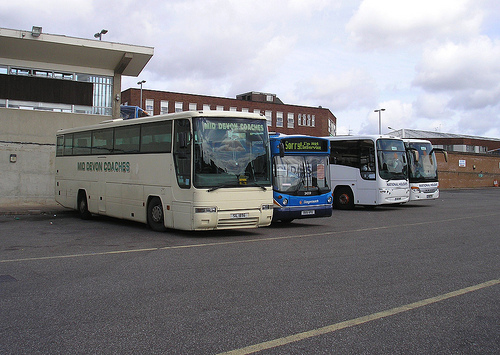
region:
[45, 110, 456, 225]
Four buses parked together.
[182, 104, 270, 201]
Large window on the white bus.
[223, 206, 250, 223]
License plate on the white bus.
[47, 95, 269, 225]
The white bus is a tour bus.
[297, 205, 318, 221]
License plate on the blue bus.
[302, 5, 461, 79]
Blue sky filled with clouds.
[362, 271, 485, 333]
White line on the road.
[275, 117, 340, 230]
Blue bus is a city bus.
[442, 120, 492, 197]
Brick building beside the buses.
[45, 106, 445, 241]
buses parked in parking lot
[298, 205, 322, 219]
license plate on front of bus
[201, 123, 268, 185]
windshield on bus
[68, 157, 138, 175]
name of bus carrier on side of bus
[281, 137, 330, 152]
digital window on front of bus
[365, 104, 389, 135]
tall street lamp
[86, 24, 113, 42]
lights on top of roof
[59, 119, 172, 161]
windows on side of bus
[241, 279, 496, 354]
white line in street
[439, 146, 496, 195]
brick wall in parking lot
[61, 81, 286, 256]
white bus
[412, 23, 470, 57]
white clouds in blue sky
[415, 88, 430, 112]
white clouds in blue sky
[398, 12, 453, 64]
white clouds in blue sky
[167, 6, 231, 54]
white clouds in blue sky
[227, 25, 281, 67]
white clouds in blue sky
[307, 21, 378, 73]
white clouds in blue sky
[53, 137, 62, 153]
window on the side of the bus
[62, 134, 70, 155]
window on the side of the bus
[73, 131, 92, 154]
window on the side of the bus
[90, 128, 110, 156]
window on the side of the bus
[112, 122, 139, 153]
window on the side of the bus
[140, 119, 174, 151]
window on the side of the bus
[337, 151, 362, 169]
window on the side of the bus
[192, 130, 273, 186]
windshield on passenger bus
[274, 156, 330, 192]
windshield on passenger bus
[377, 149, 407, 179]
windshield on passenger bus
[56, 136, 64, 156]
window on side of bus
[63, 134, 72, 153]
window on side of bus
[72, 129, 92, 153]
window on side of bus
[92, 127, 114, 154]
window on side of bus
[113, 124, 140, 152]
window on side of bus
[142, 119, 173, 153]
window on side of bus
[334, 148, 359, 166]
window on side of bus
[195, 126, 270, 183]
windshield on passenger bus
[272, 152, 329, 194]
windshield on passenger bus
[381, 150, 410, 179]
windshield on passenger bus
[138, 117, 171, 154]
A window on a vehicle.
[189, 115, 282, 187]
A window on a vehicle.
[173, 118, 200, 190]
A window on a vehicle.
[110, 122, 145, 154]
A window on a vehicle.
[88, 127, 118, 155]
A window on a vehicle.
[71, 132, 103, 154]
A window on a vehicle.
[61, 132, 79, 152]
A window on a vehicle.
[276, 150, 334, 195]
A window on a vehicle.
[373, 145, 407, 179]
A window on a vehicle.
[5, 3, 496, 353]
a scene during the day time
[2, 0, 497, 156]
a sky with clouds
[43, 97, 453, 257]
a row of buses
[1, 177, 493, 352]
a gray street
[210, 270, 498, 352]
a white line